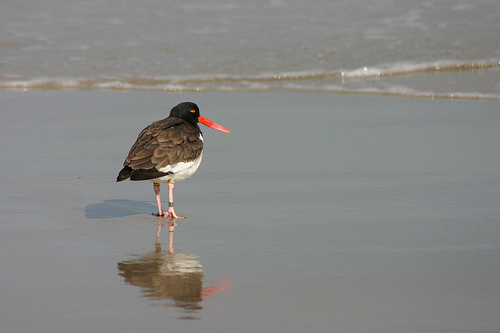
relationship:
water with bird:
[0, 2, 499, 104] [115, 100, 232, 223]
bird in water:
[115, 100, 232, 223] [0, 2, 499, 104]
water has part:
[0, 2, 499, 104] [7, 80, 32, 87]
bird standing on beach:
[115, 100, 232, 223] [2, 88, 500, 333]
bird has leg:
[115, 100, 232, 223] [163, 179, 183, 221]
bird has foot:
[115, 100, 232, 223] [164, 202, 180, 220]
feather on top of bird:
[154, 123, 186, 144] [115, 100, 232, 223]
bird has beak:
[115, 100, 232, 223] [196, 113, 233, 138]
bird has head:
[115, 100, 232, 223] [169, 100, 200, 127]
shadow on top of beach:
[81, 195, 167, 223] [2, 88, 500, 333]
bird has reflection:
[115, 100, 232, 223] [116, 216, 235, 328]